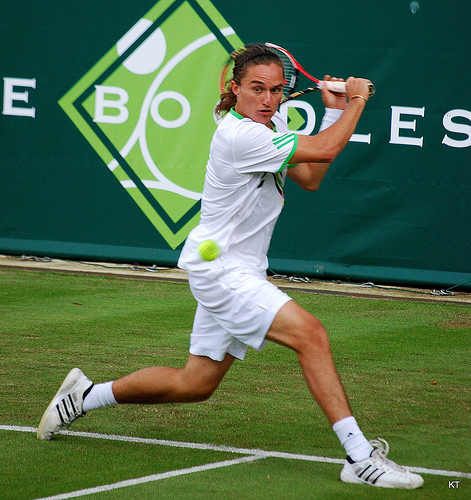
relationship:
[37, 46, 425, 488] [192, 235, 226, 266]
man hitting ball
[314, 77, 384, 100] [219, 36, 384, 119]
handle of racket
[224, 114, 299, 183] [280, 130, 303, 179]
sleeve has border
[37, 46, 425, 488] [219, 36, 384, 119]
man holds racket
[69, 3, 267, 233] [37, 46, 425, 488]
diamond behind man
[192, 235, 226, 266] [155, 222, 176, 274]
ball in air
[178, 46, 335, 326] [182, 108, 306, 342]
man has clothes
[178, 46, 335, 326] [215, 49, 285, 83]
man has hair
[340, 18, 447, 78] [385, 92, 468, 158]
wall has letters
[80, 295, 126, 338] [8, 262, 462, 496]
grass of court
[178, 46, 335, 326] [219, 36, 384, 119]
man holding racket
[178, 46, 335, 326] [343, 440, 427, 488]
man has shoe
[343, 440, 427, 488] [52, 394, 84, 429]
shoe have stripes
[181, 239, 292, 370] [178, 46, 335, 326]
shorts on man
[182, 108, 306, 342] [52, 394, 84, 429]
shirt has stripes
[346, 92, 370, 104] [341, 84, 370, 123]
band on wrist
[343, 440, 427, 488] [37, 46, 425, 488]
shoe on man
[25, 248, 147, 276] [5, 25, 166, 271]
chains holding banner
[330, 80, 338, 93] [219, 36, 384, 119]
tape on racket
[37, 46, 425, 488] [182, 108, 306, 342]
man wearing outfit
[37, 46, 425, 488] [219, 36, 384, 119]
man holding racket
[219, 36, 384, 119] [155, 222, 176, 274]
racket in air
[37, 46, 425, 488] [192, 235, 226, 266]
man swings at ball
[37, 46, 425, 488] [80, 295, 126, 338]
man on grass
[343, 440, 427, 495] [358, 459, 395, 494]
shoe with lines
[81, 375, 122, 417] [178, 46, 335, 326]
sock on man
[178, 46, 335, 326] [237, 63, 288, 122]
man has face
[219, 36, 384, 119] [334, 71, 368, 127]
racket in hand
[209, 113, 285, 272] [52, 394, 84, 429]
shirt with stripes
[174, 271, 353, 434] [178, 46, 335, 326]
legs on man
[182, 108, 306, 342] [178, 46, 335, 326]
outfit on man